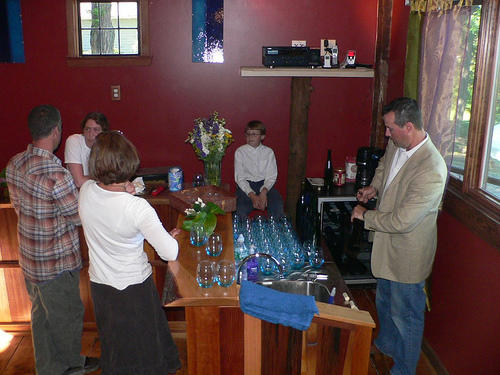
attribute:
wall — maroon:
[1, 0, 385, 144]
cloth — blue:
[236, 279, 318, 331]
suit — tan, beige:
[365, 132, 449, 277]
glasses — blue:
[189, 214, 326, 287]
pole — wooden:
[287, 76, 312, 234]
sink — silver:
[246, 275, 336, 301]